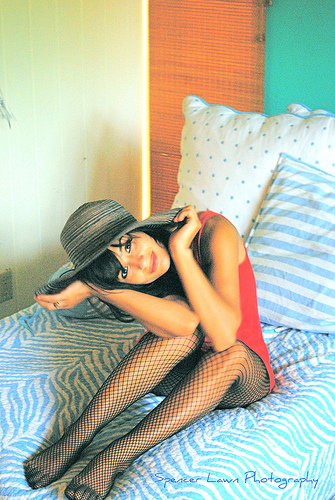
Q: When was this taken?
A: Daytime.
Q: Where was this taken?
A: Bedroom.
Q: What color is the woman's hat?
A: Gray.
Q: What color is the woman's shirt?
A: Red.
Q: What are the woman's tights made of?
A: Mesh.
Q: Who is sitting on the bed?
A: Woman.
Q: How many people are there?
A: 1.